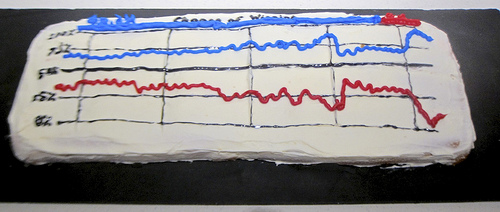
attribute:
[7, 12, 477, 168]
cake — long, rectangular, chart, large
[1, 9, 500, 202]
table — dark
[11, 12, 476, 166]
frosting — white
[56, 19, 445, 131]
lines — red, blue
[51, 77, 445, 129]
line — red, curvy, frosting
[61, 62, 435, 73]
line — black, flat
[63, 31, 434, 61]
line — blue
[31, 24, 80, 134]
numbers — black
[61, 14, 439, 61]
lines — blue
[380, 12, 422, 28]
frosting — red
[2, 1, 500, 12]
wall — white